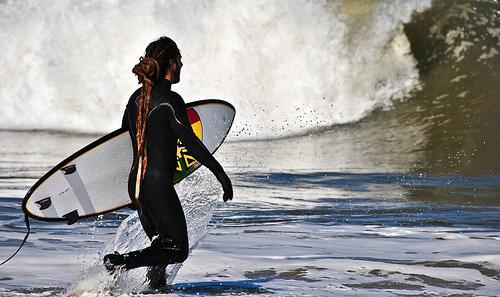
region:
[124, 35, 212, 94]
the head of a man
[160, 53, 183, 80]
the ear of a man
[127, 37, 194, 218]
dreadlocks on a man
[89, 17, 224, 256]
a man in a wet suit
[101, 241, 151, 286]
the foot of a man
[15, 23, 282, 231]
a man holding a surf board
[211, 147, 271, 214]
the hand of a man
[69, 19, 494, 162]
a really big wave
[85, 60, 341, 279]
a man in the water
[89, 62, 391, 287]
a man splashing water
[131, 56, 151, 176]
The guy's dreaded hair.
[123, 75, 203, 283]
The wet suit the surfer is wearing.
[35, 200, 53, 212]
The fin at the bottom of the surfboard.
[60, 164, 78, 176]
The fin on the left.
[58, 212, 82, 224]
The fin on the right.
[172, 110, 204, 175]
The design on the surfboard.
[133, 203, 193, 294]
The legs of the surfer.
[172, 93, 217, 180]
The arm of the surfer.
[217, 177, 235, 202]
The hand of the surfer.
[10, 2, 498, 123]
The wave in the ocean.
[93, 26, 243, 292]
this is a man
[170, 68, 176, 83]
the man is light skinned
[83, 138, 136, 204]
this is a surfboard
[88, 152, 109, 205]
the surfboard is white in color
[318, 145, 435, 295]
this is a water body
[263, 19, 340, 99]
the water is rough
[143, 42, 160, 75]
this is the hair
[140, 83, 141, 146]
the hair is long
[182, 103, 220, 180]
this is the hand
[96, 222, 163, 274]
the leg is raised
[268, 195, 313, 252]
part of a water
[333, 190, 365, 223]
part of a wave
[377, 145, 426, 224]
part of a water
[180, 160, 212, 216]
part of a hanmd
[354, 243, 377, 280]
part of a water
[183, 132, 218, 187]
part of an elbow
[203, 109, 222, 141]
part of a board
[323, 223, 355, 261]
part of a water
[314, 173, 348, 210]
part fo a water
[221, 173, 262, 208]
part of a hand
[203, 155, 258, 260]
part of a hand